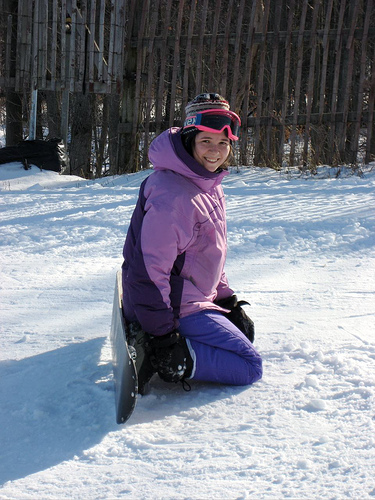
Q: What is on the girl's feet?
A: A snowboard.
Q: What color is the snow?
A: White.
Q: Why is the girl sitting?
A: She is posing for a picture.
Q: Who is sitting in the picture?
A: A girl.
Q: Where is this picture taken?
A: In a backyard.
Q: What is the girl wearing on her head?
A: Snow goggles.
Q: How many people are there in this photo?
A: One.